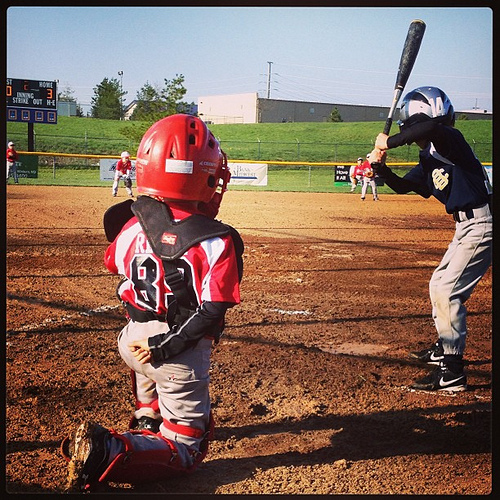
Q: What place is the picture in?
A: It is at the field.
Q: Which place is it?
A: It is a field.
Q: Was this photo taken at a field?
A: Yes, it was taken in a field.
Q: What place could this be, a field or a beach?
A: It is a field.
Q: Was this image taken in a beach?
A: No, the picture was taken in a field.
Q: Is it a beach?
A: No, it is a field.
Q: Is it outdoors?
A: Yes, it is outdoors.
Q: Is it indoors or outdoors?
A: It is outdoors.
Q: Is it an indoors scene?
A: No, it is outdoors.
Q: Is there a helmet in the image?
A: Yes, there is a helmet.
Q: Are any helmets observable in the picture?
A: Yes, there is a helmet.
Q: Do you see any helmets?
A: Yes, there is a helmet.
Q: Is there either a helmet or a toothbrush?
A: Yes, there is a helmet.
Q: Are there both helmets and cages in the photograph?
A: No, there is a helmet but no cages.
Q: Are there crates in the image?
A: No, there are no crates.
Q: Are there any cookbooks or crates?
A: No, there are no crates or cookbooks.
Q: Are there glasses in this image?
A: No, there are no glasses.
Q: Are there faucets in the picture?
A: No, there are no faucets.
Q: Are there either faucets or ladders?
A: No, there are no faucets or ladders.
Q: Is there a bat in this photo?
A: Yes, there is a bat.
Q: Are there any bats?
A: Yes, there is a bat.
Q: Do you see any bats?
A: Yes, there is a bat.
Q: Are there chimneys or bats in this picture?
A: Yes, there is a bat.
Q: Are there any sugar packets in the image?
A: No, there are no sugar packets.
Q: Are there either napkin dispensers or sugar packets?
A: No, there are no sugar packets or napkin dispensers.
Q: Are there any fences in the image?
A: Yes, there is a fence.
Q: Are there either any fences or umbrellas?
A: Yes, there is a fence.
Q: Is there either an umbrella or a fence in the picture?
A: Yes, there is a fence.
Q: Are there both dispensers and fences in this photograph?
A: No, there is a fence but no dispensers.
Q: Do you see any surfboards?
A: No, there are no surfboards.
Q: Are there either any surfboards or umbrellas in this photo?
A: No, there are no surfboards or umbrellas.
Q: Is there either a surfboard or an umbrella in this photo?
A: No, there are no surfboards or umbrellas.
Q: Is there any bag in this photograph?
A: No, there are no bags.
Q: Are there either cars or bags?
A: No, there are no bags or cars.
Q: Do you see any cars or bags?
A: No, there are no bags or cars.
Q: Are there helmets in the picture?
A: Yes, there is a helmet.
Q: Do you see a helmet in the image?
A: Yes, there is a helmet.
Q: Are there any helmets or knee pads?
A: Yes, there is a helmet.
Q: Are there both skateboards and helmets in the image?
A: No, there is a helmet but no skateboards.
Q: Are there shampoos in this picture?
A: No, there are no shampoos.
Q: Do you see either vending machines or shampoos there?
A: No, there are no shampoos or vending machines.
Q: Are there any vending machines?
A: No, there are no vending machines.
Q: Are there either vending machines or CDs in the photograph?
A: No, there are no vending machines or cds.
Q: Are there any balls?
A: No, there are no balls.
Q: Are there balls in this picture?
A: No, there are no balls.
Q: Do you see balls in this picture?
A: No, there are no balls.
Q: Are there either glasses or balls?
A: No, there are no balls or glasses.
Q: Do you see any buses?
A: No, there are no buses.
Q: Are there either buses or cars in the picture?
A: No, there are no buses or cars.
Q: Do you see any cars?
A: No, there are no cars.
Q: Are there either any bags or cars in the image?
A: No, there are no cars or bags.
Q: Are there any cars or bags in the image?
A: No, there are no cars or bags.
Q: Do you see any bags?
A: No, there are no bags.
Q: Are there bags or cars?
A: No, there are no bags or cars.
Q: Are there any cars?
A: No, there are no cars.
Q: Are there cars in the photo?
A: No, there are no cars.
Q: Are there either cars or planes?
A: No, there are no cars or planes.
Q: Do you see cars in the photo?
A: No, there are no cars.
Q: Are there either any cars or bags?
A: No, there are no cars or bags.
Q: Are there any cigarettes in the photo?
A: No, there are no cigarettes.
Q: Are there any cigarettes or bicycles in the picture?
A: No, there are no cigarettes or bicycles.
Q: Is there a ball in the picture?
A: No, there are no balls.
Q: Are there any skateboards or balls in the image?
A: No, there are no balls or skateboards.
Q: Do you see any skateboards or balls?
A: No, there are no balls or skateboards.